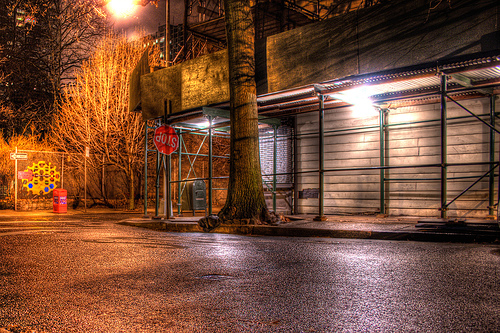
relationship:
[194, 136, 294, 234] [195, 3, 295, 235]
trunk of tree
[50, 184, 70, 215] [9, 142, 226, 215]
trash can next to fence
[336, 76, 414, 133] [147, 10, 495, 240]
light on building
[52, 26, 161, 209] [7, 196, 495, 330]
tree on ground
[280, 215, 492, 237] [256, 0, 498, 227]
sidewalk next to building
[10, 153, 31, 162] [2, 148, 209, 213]
sign on fence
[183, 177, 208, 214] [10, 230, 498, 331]
can on street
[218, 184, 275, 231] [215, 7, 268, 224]
trunk of tree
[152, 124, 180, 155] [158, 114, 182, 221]
sign hang off pole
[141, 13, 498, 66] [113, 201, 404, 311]
scaffolding above ground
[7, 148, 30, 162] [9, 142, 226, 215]
sign on fence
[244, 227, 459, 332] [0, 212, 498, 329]
reflection on ground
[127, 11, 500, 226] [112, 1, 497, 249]
building on building